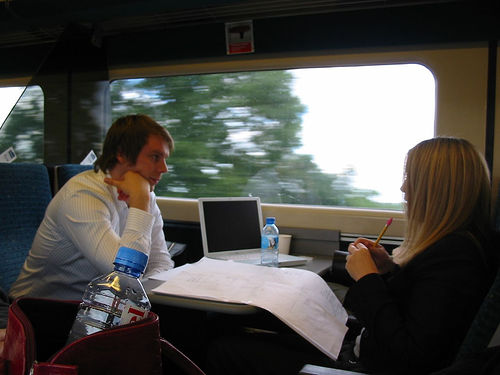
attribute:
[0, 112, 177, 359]
man — sitting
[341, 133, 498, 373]
woman — blonde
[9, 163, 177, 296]
shirt — white, black, striped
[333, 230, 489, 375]
shirt — black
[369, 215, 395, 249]
pencil — yellow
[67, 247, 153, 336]
water bottle — clear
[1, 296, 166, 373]
bag — purple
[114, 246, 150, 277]
top — blue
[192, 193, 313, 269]
laptop — silver, off, black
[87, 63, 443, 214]
window — large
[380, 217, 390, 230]
eraser — pink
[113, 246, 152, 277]
lid — blue